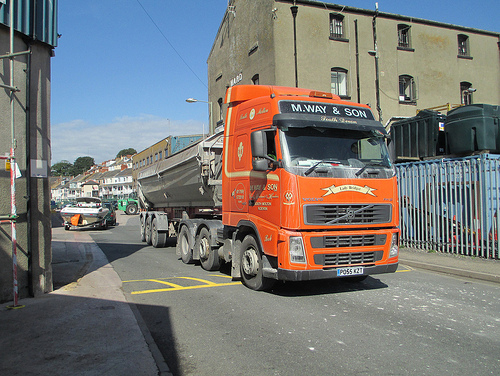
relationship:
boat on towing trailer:
[59, 196, 116, 229] [105, 187, 142, 218]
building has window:
[199, 1, 496, 151] [327, 10, 349, 43]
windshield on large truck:
[280, 127, 397, 177] [132, 84, 401, 291]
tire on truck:
[151, 217, 167, 247] [187, 77, 392, 285]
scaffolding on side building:
[3, 0, 38, 305] [3, 0, 63, 300]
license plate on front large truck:
[337, 266, 364, 276] [132, 84, 401, 291]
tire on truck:
[236, 230, 266, 296] [216, 71, 407, 287]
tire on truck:
[193, 223, 218, 270] [216, 71, 407, 287]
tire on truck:
[173, 220, 196, 268] [216, 71, 407, 287]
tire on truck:
[146, 213, 169, 252] [216, 71, 407, 287]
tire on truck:
[119, 197, 141, 227] [216, 71, 407, 287]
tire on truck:
[239, 234, 275, 290] [216, 71, 407, 287]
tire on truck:
[198, 227, 222, 271] [216, 71, 407, 287]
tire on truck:
[179, 224, 200, 263] [216, 71, 407, 287]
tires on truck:
[140, 217, 146, 242] [216, 71, 407, 287]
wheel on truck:
[126, 205, 138, 212] [216, 71, 407, 287]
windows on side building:
[328, 12, 473, 107] [206, 0, 498, 135]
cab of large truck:
[220, 86, 402, 289] [132, 84, 401, 291]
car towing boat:
[101, 195, 117, 230] [59, 193, 109, 233]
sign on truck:
[278, 100, 374, 119] [226, 94, 408, 272]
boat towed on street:
[56, 187, 124, 244] [53, 198, 494, 370]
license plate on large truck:
[335, 264, 367, 276] [132, 84, 401, 291]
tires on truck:
[140, 217, 146, 242] [128, 86, 402, 289]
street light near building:
[187, 92, 216, 132] [205, 0, 474, 108]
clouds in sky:
[54, 113, 135, 143] [59, 18, 151, 82]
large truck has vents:
[132, 84, 401, 291] [301, 197, 395, 272]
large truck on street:
[132, 84, 401, 291] [90, 214, 484, 371]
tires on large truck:
[135, 208, 267, 294] [132, 84, 401, 291]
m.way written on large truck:
[288, 100, 328, 115] [132, 84, 401, 291]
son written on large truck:
[343, 106, 369, 117] [132, 84, 401, 291]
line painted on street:
[130, 279, 240, 293] [90, 214, 484, 371]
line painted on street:
[209, 274, 232, 278] [90, 214, 484, 371]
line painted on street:
[158, 272, 217, 285] [90, 214, 484, 371]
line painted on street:
[208, 270, 232, 279] [90, 214, 484, 371]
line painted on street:
[122, 279, 183, 288] [90, 214, 484, 371]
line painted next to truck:
[209, 274, 232, 278] [125, 69, 439, 305]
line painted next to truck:
[174, 272, 214, 282] [125, 69, 439, 305]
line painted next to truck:
[130, 279, 240, 293] [125, 69, 439, 305]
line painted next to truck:
[120, 274, 183, 283] [125, 69, 439, 305]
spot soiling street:
[308, 345, 316, 350] [90, 214, 484, 371]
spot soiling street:
[336, 338, 346, 346] [90, 214, 484, 371]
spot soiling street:
[377, 303, 385, 311] [90, 214, 484, 371]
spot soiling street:
[445, 325, 454, 333] [90, 214, 484, 371]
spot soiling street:
[390, 293, 399, 297] [90, 214, 484, 371]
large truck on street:
[132, 82, 406, 296] [236, 305, 461, 373]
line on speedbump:
[131, 281, 242, 294] [101, 242, 430, 305]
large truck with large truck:
[132, 84, 401, 291] [132, 84, 401, 291]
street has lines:
[95, 237, 499, 369] [119, 273, 241, 295]